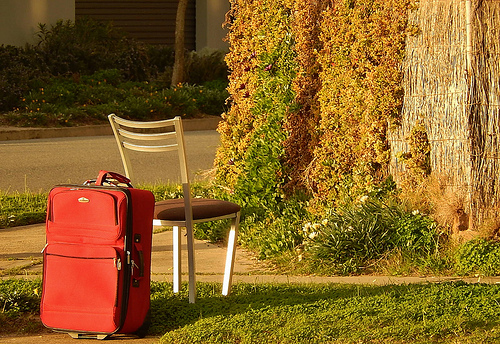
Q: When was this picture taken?
A: Daytime.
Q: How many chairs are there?
A: One.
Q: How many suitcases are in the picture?
A: One.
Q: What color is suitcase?
A: Red.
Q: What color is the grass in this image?
A: Green.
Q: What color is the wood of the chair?
A: White.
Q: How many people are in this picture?
A: Zero.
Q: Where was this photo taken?
A: In front of a tree.